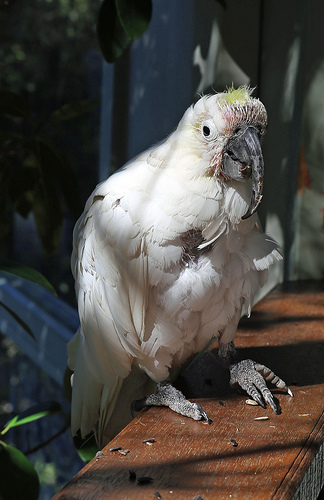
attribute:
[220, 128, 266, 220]
beak — sharp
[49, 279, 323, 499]
platform — wood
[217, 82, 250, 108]
feathers — yellow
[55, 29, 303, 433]
feathers — white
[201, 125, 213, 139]
eye ball — black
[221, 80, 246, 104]
hair — yellow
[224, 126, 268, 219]
beak — black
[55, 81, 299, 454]
parrot — white, old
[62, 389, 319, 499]
panel — wooden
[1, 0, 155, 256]
leaves — large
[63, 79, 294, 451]
bird — sick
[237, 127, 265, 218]
beak — curved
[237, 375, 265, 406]
claw — gray, black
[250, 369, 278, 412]
claw — gray, black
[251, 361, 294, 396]
claw — gray, black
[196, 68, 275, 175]
feathers — yellow